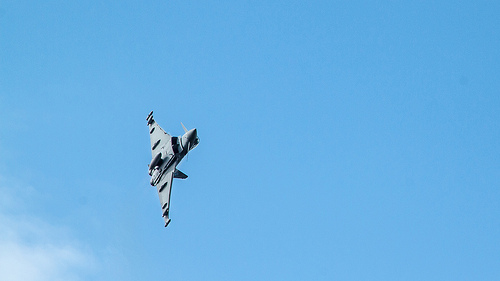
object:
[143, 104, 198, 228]
jet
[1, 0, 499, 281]
sky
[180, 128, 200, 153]
front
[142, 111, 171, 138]
wing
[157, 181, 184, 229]
wing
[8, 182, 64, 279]
cloud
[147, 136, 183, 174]
body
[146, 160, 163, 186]
tail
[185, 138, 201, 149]
cockpit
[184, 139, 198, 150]
window